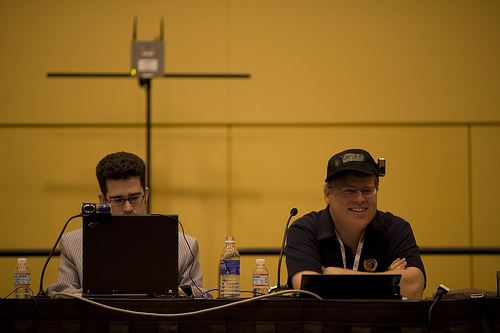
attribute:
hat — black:
[325, 145, 379, 195]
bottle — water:
[245, 247, 293, 301]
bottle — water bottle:
[217, 235, 239, 297]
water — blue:
[219, 233, 244, 303]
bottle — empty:
[244, 257, 274, 294]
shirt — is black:
[283, 208, 427, 302]